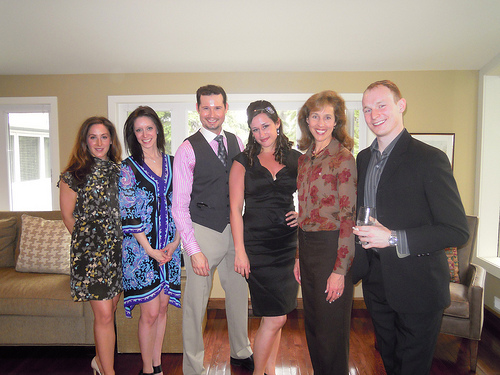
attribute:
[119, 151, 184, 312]
blue dress — paisley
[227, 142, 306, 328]
dress — black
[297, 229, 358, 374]
pants — black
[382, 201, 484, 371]
chair — behind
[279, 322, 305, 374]
floor — hardwood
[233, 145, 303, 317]
dress — black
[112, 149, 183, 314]
dress — black, blue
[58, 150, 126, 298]
dress — black, multicolored , dotted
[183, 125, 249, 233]
vest — striped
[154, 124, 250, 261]
shirt — pink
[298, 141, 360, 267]
blouse — fabric, autumn leaves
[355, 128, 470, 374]
suit — black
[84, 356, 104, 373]
shoe — white, high heel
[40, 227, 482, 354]
floor — hardwood, dark brown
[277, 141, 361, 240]
shirt — floral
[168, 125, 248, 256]
long sleeve — pink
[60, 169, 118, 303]
dress — colorful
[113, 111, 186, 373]
woman — beautiful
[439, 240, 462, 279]
pillow — decorative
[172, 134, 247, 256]
shirt — striped